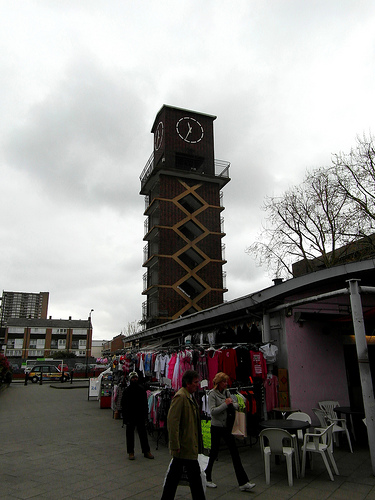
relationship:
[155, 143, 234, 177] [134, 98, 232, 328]
railings along tower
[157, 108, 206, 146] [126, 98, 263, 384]
clock along tower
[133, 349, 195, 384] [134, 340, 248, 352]
clothing on racks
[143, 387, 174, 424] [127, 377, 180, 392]
clothing on racks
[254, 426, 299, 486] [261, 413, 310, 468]
chair sitting at table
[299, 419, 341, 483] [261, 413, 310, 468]
chair sitting at table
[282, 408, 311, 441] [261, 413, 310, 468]
chair sitting at table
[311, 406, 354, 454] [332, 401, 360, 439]
chair sitting at table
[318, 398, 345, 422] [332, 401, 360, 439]
chair sitting at table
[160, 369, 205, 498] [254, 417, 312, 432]
man walking past table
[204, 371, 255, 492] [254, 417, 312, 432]
pedestrian walking past table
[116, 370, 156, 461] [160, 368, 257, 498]
man watching couple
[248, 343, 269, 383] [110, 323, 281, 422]
clothing hanging on rack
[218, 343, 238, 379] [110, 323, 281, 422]
clothing hanging on rack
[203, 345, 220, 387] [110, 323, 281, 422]
clothing hanging on rack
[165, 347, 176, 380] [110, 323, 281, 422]
clothing hanging on rack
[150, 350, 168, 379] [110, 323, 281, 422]
clothing hanging on rack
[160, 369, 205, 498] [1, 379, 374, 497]
man walking on walk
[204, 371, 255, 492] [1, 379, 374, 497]
pedestrian walking on walk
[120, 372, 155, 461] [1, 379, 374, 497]
man walking on walk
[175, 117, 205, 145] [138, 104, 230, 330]
clock built into tall tower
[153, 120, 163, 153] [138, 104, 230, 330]
clock built into tall tower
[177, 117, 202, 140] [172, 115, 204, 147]
face belonging to clock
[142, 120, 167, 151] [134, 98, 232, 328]
clock built into tower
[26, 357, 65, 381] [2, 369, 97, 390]
bush parked on street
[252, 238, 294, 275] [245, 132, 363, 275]
branch growing on tree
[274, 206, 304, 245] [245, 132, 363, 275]
branch growing on tree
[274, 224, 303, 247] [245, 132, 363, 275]
branch growing on tree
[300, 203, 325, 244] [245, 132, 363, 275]
branch growing on tree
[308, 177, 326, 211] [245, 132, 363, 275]
branch growing on tree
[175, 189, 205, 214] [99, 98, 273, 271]
section decorating tower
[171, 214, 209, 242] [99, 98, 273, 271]
section decorating tower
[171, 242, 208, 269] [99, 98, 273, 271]
section decorating tower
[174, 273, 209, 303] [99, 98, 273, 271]
section decorating tower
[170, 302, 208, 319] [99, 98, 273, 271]
section decorating tower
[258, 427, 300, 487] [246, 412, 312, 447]
chair around table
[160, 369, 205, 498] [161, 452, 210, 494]
man with shopping bag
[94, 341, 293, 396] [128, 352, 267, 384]
rack of clothes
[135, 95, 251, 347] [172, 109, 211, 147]
tall tower with clock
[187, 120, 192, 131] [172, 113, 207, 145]
hour hand on clock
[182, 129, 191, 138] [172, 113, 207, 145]
minute hand on clock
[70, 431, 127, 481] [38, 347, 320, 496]
tiles on ground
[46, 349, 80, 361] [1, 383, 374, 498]
bush on sidewalk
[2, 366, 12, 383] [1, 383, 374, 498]
bush on sidewalk